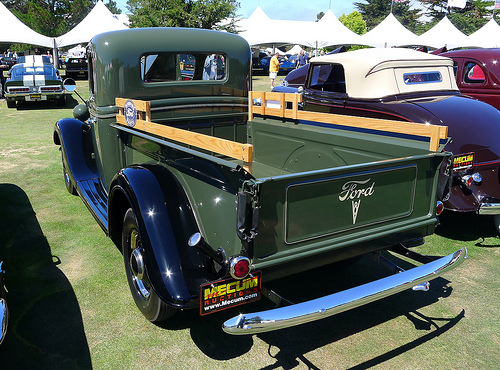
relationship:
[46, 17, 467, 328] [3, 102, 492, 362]
truck on grass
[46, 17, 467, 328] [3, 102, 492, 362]
truck on top of grass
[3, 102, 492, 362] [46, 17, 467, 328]
grass under truck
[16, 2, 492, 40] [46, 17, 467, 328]
sky above truck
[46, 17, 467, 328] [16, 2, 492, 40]
truck under sky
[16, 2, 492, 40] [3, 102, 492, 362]
sky above grass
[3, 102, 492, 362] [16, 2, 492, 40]
grass under sky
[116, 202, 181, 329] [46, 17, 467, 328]
wheel on truck